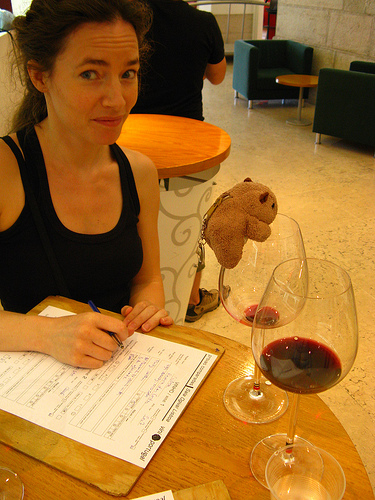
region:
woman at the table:
[5, 2, 189, 409]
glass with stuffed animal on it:
[195, 182, 302, 418]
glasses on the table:
[214, 204, 361, 487]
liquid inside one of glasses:
[257, 336, 341, 386]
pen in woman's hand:
[79, 291, 129, 347]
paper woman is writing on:
[5, 301, 215, 454]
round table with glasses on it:
[12, 295, 362, 480]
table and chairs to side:
[235, 29, 374, 151]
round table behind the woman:
[7, 94, 240, 179]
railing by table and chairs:
[190, 2, 271, 50]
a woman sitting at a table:
[7, 7, 173, 476]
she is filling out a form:
[24, 292, 192, 482]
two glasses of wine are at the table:
[201, 194, 366, 445]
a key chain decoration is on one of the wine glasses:
[180, 179, 283, 270]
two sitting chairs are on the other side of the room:
[237, 28, 369, 153]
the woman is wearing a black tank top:
[0, 123, 141, 319]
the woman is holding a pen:
[81, 288, 130, 358]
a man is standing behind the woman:
[146, 5, 234, 319]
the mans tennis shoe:
[185, 287, 226, 323]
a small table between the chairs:
[276, 53, 319, 126]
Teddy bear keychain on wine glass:
[192, 167, 303, 417]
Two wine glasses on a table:
[187, 174, 353, 489]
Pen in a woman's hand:
[40, 303, 123, 363]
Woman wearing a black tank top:
[0, 0, 180, 366]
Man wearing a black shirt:
[121, 0, 228, 121]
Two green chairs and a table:
[226, 30, 365, 136]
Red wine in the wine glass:
[245, 250, 355, 484]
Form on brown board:
[0, 290, 225, 493]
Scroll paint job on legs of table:
[105, 108, 227, 324]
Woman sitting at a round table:
[2, 0, 366, 499]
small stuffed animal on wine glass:
[191, 163, 274, 276]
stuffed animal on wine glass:
[170, 170, 314, 339]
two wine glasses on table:
[189, 175, 364, 499]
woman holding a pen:
[27, 271, 174, 379]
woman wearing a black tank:
[0, 119, 185, 330]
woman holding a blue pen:
[71, 286, 136, 377]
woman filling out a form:
[1, 261, 237, 481]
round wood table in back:
[101, 95, 254, 227]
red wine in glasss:
[255, 333, 348, 405]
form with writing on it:
[4, 268, 225, 480]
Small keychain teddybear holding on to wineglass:
[181, 152, 304, 437]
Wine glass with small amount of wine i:
[215, 245, 373, 488]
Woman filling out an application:
[13, 8, 187, 392]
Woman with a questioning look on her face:
[3, 8, 201, 384]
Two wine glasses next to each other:
[172, 41, 368, 489]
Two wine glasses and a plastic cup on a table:
[195, 156, 363, 492]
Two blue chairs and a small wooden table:
[210, 4, 365, 154]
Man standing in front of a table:
[146, 0, 255, 346]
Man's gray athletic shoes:
[171, 274, 231, 335]